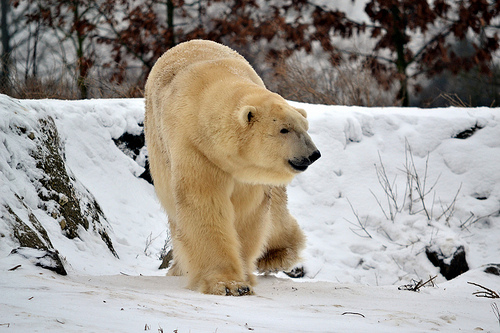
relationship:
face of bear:
[268, 109, 320, 169] [143, 38, 321, 296]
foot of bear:
[191, 259, 263, 304] [115, 50, 387, 281]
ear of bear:
[238, 105, 258, 129] [143, 38, 321, 296]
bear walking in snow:
[143, 38, 321, 296] [2, 72, 499, 329]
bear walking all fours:
[143, 38, 321, 296] [155, 184, 325, 274]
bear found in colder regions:
[106, 18, 421, 325] [340, 39, 491, 175]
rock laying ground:
[394, 237, 482, 302] [335, 243, 474, 331]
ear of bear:
[238, 105, 258, 129] [145, 44, 311, 301]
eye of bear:
[278, 126, 294, 139] [144, 52, 304, 287]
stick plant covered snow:
[341, 153, 491, 311] [323, 134, 499, 316]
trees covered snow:
[0, 0, 497, 106] [332, 122, 448, 175]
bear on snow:
[143, 38, 321, 296] [384, 96, 497, 223]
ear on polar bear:
[236, 103, 256, 137] [145, 43, 282, 270]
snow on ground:
[346, 155, 434, 244] [85, 257, 303, 332]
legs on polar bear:
[168, 186, 258, 284] [145, 43, 282, 270]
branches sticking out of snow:
[341, 153, 475, 263] [341, 130, 475, 268]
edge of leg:
[194, 283, 250, 293] [171, 153, 251, 296]